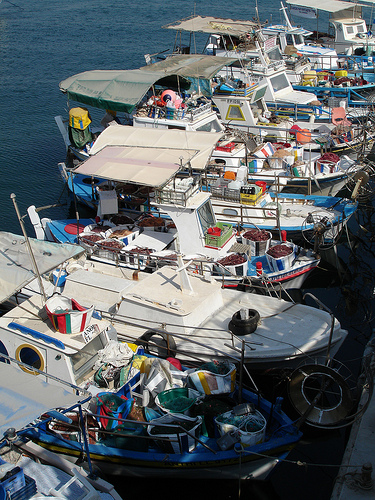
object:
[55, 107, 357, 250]
boat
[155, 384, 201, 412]
basket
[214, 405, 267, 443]
bag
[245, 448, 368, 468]
rope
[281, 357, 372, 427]
ring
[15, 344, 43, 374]
window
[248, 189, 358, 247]
front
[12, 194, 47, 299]
antenna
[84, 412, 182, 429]
pole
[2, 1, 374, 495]
water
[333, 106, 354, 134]
chair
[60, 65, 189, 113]
canopy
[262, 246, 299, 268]
box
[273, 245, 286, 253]
lobsters